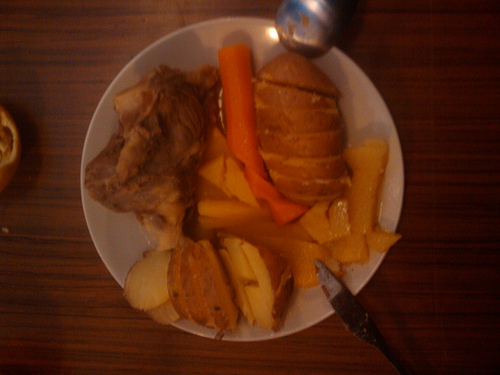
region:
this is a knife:
[312, 259, 419, 374]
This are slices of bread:
[267, 62, 349, 204]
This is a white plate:
[74, 28, 408, 338]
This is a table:
[7, 15, 497, 373]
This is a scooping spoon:
[269, 5, 341, 54]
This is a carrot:
[219, 44, 251, 169]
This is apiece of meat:
[91, 61, 188, 230]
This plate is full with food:
[81, 18, 439, 336]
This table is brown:
[8, 4, 488, 373]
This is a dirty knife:
[311, 261, 415, 373]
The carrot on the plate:
[211, 33, 306, 224]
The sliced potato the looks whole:
[251, 55, 348, 205]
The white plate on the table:
[67, 7, 404, 339]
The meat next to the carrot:
[82, 61, 222, 246]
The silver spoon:
[270, 0, 341, 60]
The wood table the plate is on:
[1, 0, 498, 374]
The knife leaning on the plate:
[312, 257, 410, 374]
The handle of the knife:
[375, 338, 423, 373]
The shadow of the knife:
[367, 276, 428, 369]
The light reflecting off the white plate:
[263, 22, 282, 48]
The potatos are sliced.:
[107, 218, 343, 330]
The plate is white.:
[144, 36, 318, 62]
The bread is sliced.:
[268, 69, 326, 176]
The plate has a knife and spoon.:
[263, 7, 389, 320]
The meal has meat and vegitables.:
[117, 73, 264, 245]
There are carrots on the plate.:
[219, 50, 277, 206]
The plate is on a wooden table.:
[16, 223, 81, 360]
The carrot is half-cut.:
[218, 59, 277, 201]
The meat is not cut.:
[107, 88, 188, 200]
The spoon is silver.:
[277, 7, 350, 51]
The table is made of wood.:
[411, 82, 479, 249]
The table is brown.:
[431, 90, 485, 252]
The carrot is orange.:
[212, 18, 286, 213]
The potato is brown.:
[253, 52, 360, 202]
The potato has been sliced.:
[247, 45, 355, 215]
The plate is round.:
[75, 14, 409, 357]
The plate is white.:
[73, 15, 407, 339]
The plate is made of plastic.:
[80, 17, 402, 341]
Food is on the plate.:
[76, 15, 413, 344]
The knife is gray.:
[306, 242, 430, 369]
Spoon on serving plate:
[256, 0, 381, 78]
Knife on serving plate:
[308, 257, 403, 373]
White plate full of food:
[65, 16, 417, 342]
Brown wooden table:
[407, 35, 494, 363]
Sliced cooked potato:
[109, 233, 307, 343]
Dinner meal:
[56, 5, 438, 354]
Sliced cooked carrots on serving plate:
[226, 162, 296, 227]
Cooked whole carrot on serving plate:
[215, 32, 270, 177]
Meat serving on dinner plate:
[62, 30, 209, 247]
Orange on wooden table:
[1, 102, 33, 222]